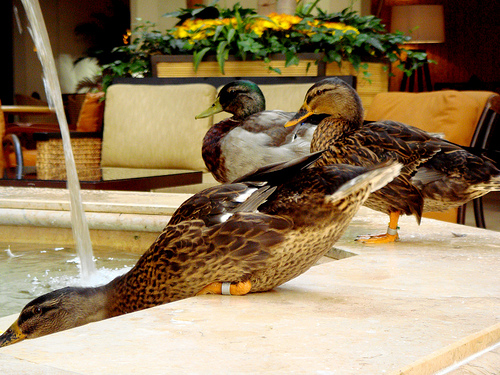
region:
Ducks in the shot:
[5, 17, 476, 353]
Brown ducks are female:
[6, 82, 495, 348]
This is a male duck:
[175, 64, 286, 177]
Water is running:
[8, 2, 125, 282]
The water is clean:
[5, 230, 127, 300]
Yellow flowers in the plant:
[83, 1, 443, 105]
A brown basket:
[22, 117, 127, 189]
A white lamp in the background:
[383, 4, 455, 94]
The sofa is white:
[80, 57, 395, 202]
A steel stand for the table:
[5, 127, 34, 185]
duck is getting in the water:
[37, 185, 382, 340]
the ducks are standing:
[199, 42, 463, 257]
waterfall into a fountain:
[9, 12, 203, 342]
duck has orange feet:
[363, 206, 414, 260]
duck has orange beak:
[279, 94, 314, 136]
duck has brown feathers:
[149, 192, 303, 299]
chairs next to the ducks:
[59, 43, 261, 235]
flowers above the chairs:
[139, 3, 405, 97]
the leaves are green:
[247, 20, 337, 56]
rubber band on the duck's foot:
[206, 263, 253, 313]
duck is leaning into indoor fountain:
[0, 149, 402, 346]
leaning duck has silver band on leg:
[194, 277, 253, 297]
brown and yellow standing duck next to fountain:
[283, 77, 498, 245]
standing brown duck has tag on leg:
[284, 75, 499, 245]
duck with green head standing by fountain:
[195, 78, 333, 185]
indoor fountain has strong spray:
[19, 0, 100, 287]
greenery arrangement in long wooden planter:
[97, 0, 437, 104]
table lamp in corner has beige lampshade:
[390, 4, 448, 90]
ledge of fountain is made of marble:
[0, 184, 498, 374]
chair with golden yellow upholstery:
[362, 89, 498, 228]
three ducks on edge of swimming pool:
[0, 62, 496, 358]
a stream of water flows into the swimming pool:
[21, 1, 122, 297]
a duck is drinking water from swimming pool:
[0, 148, 397, 372]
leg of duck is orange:
[198, 273, 255, 301]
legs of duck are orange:
[350, 210, 405, 252]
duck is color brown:
[0, 143, 412, 342]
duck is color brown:
[275, 71, 499, 254]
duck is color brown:
[188, 73, 309, 178]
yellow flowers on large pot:
[116, 0, 403, 81]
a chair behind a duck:
[356, 79, 495, 224]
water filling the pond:
[10, 2, 117, 284]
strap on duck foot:
[213, 275, 235, 295]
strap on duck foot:
[388, 227, 395, 234]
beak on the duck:
[284, 108, 310, 126]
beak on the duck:
[193, 99, 220, 120]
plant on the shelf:
[144, 7, 401, 69]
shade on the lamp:
[388, 5, 449, 44]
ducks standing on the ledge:
[170, 66, 497, 246]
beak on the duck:
[0, 323, 26, 343]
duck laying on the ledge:
[1, 148, 403, 352]